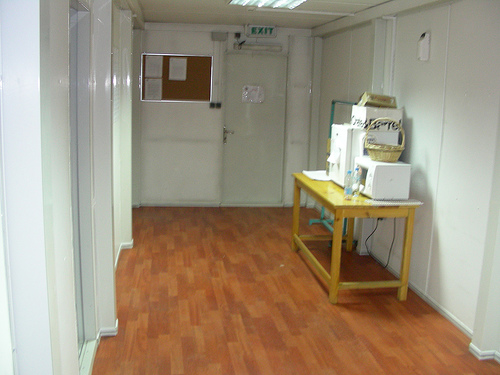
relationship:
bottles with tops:
[344, 171, 353, 200] [344, 166, 356, 173]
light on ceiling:
[220, 1, 308, 12] [140, 2, 403, 37]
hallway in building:
[113, 17, 408, 368] [5, 57, 496, 375]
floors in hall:
[87, 185, 496, 375] [156, 215, 293, 347]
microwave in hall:
[350, 157, 410, 204] [1, 58, 499, 375]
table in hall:
[291, 170, 424, 305] [150, 223, 330, 344]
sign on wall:
[249, 23, 274, 39] [305, 70, 495, 372]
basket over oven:
[359, 127, 420, 167] [355, 157, 432, 198]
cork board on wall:
[142, 55, 212, 101] [143, 21, 220, 203]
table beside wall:
[283, 168, 423, 303] [305, 1, 499, 364]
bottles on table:
[344, 171, 353, 200] [292, 159, 421, 303]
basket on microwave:
[365, 117, 406, 163] [353, 149, 412, 204]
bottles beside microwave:
[344, 172, 354, 199] [350, 152, 413, 202]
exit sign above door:
[248, 26, 278, 37] [212, 46, 289, 207]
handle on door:
[218, 126, 239, 145] [222, 44, 294, 212]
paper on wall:
[407, 31, 437, 65] [305, 70, 495, 372]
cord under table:
[363, 219, 402, 268] [283, 168, 423, 303]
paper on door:
[140, 77, 176, 98] [199, 32, 404, 283]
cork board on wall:
[136, 47, 218, 104] [143, 21, 220, 203]